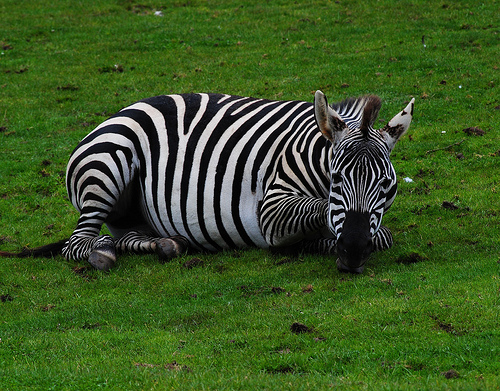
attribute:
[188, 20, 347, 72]
grass — green, ripped, diveted, covering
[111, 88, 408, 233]
zebra — laying, black, lying, striped, here, resting, tired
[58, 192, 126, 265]
legs — bent, tucked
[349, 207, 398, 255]
nose — black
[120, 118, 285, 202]
stripes — black, here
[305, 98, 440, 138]
ears — black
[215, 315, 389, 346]
dirt — clodded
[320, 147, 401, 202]
eyes — black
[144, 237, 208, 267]
hoof — black, gray